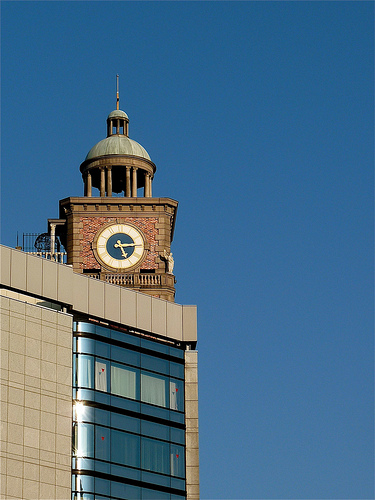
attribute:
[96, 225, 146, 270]
face — 5:15, blue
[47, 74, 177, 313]
tower — clock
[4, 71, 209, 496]
building — tan, juxtaposed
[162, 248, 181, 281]
statue — small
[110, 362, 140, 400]
window — curtained, blue, glass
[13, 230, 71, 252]
fence — metal, iron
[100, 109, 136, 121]
dome — small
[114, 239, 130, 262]
hand — hour, gold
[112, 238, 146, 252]
hand — minute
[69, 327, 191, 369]
trim — black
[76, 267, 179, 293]
railing — brown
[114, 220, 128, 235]
numeral — roman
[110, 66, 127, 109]
pole — empty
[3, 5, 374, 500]
sky — dark blue, clear, empty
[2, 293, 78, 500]
wall — brick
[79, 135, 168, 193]
dome — large